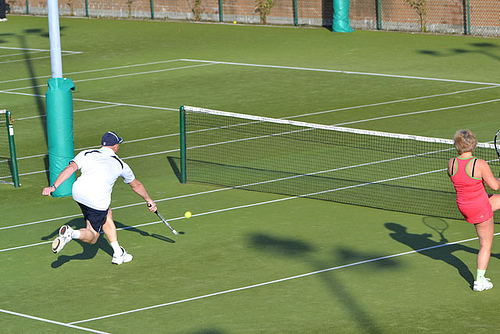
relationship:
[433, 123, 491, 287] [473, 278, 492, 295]
woman has shoes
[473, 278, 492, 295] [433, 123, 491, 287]
shoes of woman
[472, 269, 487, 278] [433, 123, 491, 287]
socks of woman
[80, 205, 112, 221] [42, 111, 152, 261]
shorts of man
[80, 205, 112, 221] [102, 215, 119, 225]
shorts of blue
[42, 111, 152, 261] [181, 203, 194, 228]
man hitting ball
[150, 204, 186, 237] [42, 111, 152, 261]
racket of man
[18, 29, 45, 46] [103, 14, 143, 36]
shadow on ground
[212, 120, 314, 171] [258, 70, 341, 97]
net of court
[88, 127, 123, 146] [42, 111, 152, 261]
hat of man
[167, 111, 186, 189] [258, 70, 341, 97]
pole between court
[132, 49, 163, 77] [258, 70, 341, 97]
line on court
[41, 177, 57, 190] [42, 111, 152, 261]
watch of man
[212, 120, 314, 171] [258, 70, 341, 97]
net on court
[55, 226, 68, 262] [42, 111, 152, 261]
foot of man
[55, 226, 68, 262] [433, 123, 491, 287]
foot of woman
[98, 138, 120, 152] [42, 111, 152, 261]
head of man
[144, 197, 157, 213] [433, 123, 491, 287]
hand of woman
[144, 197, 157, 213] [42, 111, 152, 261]
hand of man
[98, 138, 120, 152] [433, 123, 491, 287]
head of woman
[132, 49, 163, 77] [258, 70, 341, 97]
line of court